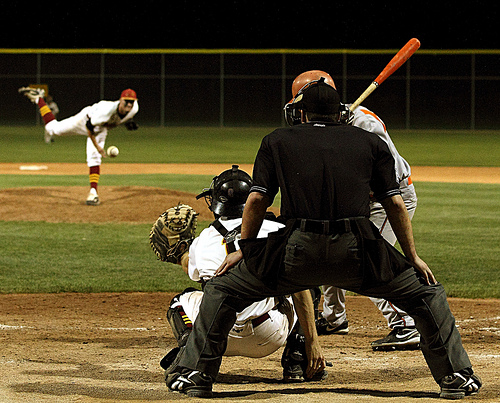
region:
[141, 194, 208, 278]
Glove on a baseball player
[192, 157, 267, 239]
Black helmet on a baseball player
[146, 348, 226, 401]
Black shoe on a umpire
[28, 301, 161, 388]
Brown dirt on a baseball field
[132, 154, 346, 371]
Baseball catcher crouching down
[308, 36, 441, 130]
Red and brown bat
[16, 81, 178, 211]
Pitcher raising his leg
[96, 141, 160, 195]
White baseball flying in the air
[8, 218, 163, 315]
Green grass on a baseball field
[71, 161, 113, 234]
Red and yellow socks on a man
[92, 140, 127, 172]
baseball flying through the air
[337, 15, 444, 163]
wooden baseball bat being held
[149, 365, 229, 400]
white and black shoes of the umpire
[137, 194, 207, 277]
catchers mitt being used to catch a ball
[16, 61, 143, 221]
baseball player leaning forward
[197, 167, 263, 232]
helmet of the catcher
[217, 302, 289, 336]
brown belt being worn with pants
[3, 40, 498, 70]
yellow edge of the fence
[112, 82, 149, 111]
red baseball cap worn by the pitcher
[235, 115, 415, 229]
black shirt worn by the umpire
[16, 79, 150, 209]
pictcher bent forward on mound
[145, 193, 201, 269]
catcher's mitt on hand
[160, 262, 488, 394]
spread legs of umpire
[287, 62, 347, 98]
red helmet on batter's head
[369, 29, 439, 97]
red top of baseball bat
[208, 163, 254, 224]
helmet on catcher's head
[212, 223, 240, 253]
strap of chest plate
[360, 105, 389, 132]
number on batter's back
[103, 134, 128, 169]
midair baseball heading to batter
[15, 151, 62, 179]
second base in the dirt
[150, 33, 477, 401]
home plate at a baseball game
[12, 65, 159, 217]
pitcher at a baseball game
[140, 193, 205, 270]
baseball player's catcher's mit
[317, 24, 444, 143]
baseball bat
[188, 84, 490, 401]
baseball umpire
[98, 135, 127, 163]
baseball in motion thrown by pitcher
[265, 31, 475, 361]
baseball batter about to swing at a pitch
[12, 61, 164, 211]
pitcher completing his windup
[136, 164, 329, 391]
baseball player playing catcher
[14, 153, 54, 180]
second base bag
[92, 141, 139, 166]
baseball heading toward homeplate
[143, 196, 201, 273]
mitt on catcher's hand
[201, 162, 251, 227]
backwards helmet on catcher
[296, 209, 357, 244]
belt on umpire's pants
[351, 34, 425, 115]
bat with red top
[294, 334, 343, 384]
catcher's hand on shoe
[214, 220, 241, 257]
straps on back of catcher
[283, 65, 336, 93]
red helmet on batter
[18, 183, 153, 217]
dirt on pitcher's mound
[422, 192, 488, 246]
green grass on field